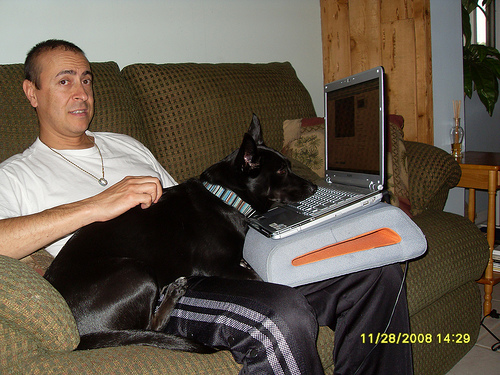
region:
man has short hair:
[18, 44, 102, 76]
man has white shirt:
[5, 101, 148, 233]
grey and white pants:
[123, 251, 405, 373]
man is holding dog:
[34, 131, 284, 327]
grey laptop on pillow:
[248, 99, 403, 242]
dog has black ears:
[234, 124, 285, 168]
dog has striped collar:
[196, 167, 251, 227]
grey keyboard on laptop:
[273, 165, 342, 204]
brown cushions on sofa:
[119, 63, 324, 163]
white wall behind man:
[73, 6, 274, 76]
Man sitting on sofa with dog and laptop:
[0, 36, 424, 373]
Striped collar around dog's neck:
[198, 174, 258, 217]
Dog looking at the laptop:
[202, 64, 403, 241]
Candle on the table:
[448, 99, 468, 158]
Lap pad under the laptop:
[241, 195, 428, 290]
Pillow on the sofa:
[281, 112, 406, 204]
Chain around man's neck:
[38, 130, 111, 187]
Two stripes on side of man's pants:
[155, 282, 300, 373]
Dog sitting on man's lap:
[0, 37, 418, 374]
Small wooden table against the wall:
[448, 150, 498, 319]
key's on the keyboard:
[287, 187, 364, 218]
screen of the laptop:
[323, 58, 387, 193]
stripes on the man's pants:
[159, 287, 304, 369]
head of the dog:
[223, 117, 320, 214]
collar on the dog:
[201, 176, 257, 226]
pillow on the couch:
[2, 242, 88, 372]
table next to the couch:
[432, 147, 497, 324]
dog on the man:
[39, 109, 324, 364]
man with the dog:
[8, 48, 297, 369]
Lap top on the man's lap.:
[135, 34, 435, 296]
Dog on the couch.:
[9, 82, 334, 369]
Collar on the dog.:
[98, 87, 402, 323]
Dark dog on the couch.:
[45, 122, 322, 329]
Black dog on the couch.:
[16, 131, 197, 358]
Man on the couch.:
[25, 26, 317, 349]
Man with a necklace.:
[28, 38, 155, 214]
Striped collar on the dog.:
[153, 127, 255, 244]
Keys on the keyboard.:
[220, 107, 365, 233]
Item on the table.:
[406, 72, 485, 158]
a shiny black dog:
[42, 113, 317, 355]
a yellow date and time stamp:
[359, 331, 471, 343]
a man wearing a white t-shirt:
[2, 37, 412, 372]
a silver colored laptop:
[247, 66, 389, 239]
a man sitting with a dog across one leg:
[1, 38, 412, 373]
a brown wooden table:
[456, 156, 499, 316]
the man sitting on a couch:
[1, 38, 487, 373]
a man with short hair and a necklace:
[3, 40, 410, 372]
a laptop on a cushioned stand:
[242, 67, 432, 286]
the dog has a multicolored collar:
[45, 112, 317, 352]